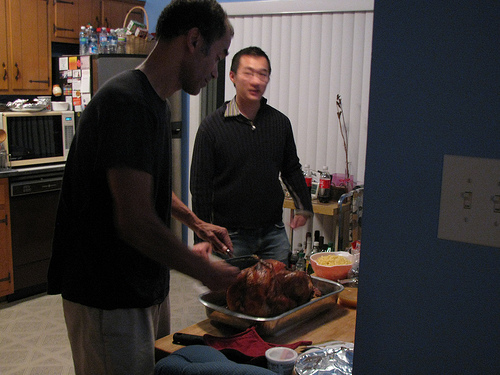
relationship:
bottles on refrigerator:
[74, 21, 133, 58] [58, 56, 183, 246]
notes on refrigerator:
[60, 57, 89, 114] [58, 56, 183, 246]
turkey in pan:
[226, 254, 321, 316] [199, 273, 342, 333]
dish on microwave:
[9, 105, 49, 113] [0, 107, 76, 171]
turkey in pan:
[209, 251, 351, 307] [197, 273, 340, 340]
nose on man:
[248, 76, 263, 86] [185, 34, 315, 272]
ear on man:
[183, 23, 205, 55] [47, 0, 240, 375]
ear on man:
[224, 66, 238, 85] [191, 47, 312, 261]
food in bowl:
[313, 251, 353, 271] [308, 249, 355, 279]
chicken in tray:
[213, 249, 325, 321] [193, 266, 346, 336]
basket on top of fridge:
[106, 11, 218, 85] [67, 36, 167, 104]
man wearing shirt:
[49, 2, 237, 340] [32, 64, 203, 311]